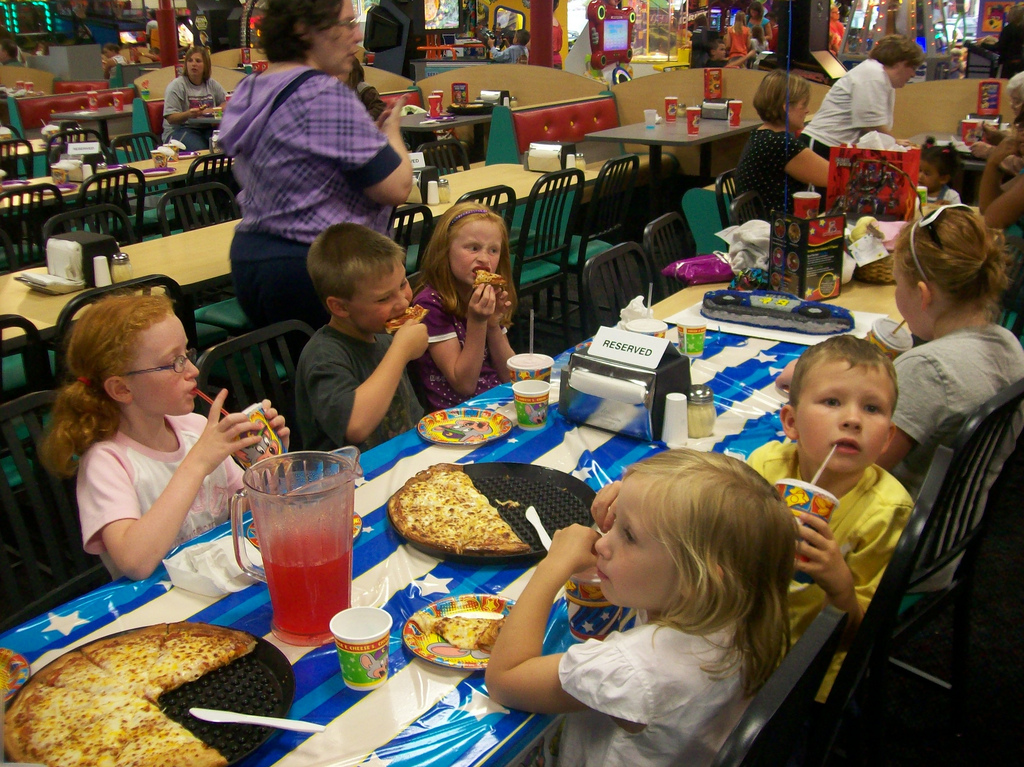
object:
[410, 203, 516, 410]
person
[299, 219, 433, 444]
boy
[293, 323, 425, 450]
shirt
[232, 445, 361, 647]
pitcher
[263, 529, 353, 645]
drink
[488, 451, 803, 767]
girl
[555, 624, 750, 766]
shirt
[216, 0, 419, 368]
woman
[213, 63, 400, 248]
shirt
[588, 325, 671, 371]
sign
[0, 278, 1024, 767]
table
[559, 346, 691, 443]
napkin holder